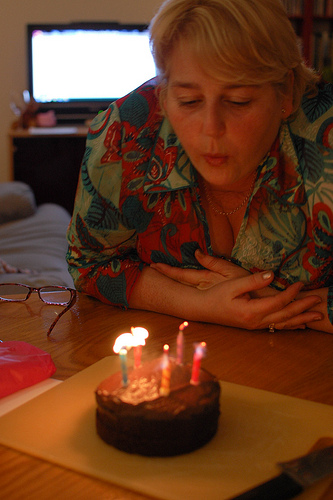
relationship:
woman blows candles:
[65, 0, 333, 332] [108, 310, 213, 394]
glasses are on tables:
[10, 274, 88, 329] [62, 295, 263, 369]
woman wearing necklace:
[68, 28, 331, 256] [148, 85, 310, 222]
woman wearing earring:
[65, 0, 333, 332] [276, 106, 292, 120]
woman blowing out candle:
[65, 0, 333, 332] [189, 341, 206, 387]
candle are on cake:
[189, 341, 206, 387] [82, 338, 242, 440]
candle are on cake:
[113, 332, 131, 388] [92, 305, 234, 460]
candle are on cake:
[189, 341, 206, 387] [86, 383, 222, 458]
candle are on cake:
[189, 341, 206, 387] [51, 309, 261, 463]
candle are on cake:
[189, 341, 206, 387] [92, 320, 219, 458]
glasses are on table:
[0, 282, 78, 337] [5, 279, 112, 373]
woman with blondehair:
[65, 0, 333, 332] [148, 0, 322, 118]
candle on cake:
[188, 340, 206, 385] [93, 355, 220, 457]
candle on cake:
[174, 320, 189, 367] [93, 355, 220, 457]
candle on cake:
[159, 342, 172, 397] [93, 355, 220, 457]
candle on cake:
[112, 331, 135, 389] [93, 355, 220, 457]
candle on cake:
[127, 326, 149, 376] [93, 355, 220, 457]